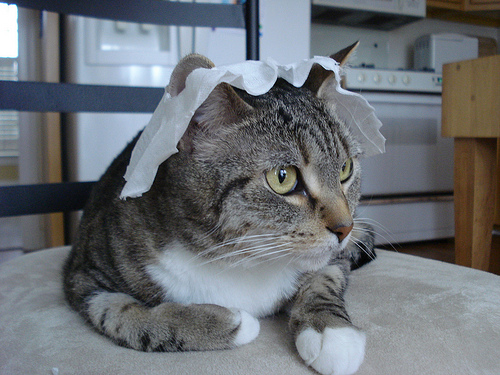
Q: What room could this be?
A: It is a kitchen.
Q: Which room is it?
A: It is a kitchen.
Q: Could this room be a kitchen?
A: Yes, it is a kitchen.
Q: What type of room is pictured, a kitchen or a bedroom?
A: It is a kitchen.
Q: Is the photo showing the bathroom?
A: No, the picture is showing the kitchen.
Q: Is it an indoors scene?
A: Yes, it is indoors.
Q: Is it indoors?
A: Yes, it is indoors.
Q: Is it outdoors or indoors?
A: It is indoors.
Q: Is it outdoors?
A: No, it is indoors.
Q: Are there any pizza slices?
A: No, there are no pizza slices.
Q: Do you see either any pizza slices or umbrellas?
A: No, there are no pizza slices or umbrellas.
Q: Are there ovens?
A: Yes, there is an oven.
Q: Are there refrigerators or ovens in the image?
A: Yes, there is an oven.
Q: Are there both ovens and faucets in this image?
A: No, there is an oven but no faucets.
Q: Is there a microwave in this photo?
A: No, there are no microwaves.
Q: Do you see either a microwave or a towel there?
A: No, there are no microwaves or towels.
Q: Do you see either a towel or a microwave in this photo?
A: No, there are no microwaves or towels.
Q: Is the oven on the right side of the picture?
A: Yes, the oven is on the right of the image.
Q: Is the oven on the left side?
A: No, the oven is on the right of the image.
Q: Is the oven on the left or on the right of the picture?
A: The oven is on the right of the image.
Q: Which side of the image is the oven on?
A: The oven is on the right of the image.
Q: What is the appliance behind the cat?
A: The appliance is an oven.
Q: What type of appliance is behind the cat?
A: The appliance is an oven.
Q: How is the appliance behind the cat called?
A: The appliance is an oven.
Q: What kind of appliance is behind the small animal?
A: The appliance is an oven.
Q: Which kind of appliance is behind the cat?
A: The appliance is an oven.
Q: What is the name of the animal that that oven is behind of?
A: The animal is a cat.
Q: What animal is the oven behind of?
A: The oven is behind the cat.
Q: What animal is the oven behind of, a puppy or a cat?
A: The oven is behind a cat.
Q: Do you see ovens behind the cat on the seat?
A: Yes, there is an oven behind the cat.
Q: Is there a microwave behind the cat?
A: No, there is an oven behind the cat.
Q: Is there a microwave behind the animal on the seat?
A: No, there is an oven behind the cat.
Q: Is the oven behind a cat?
A: Yes, the oven is behind a cat.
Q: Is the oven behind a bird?
A: No, the oven is behind a cat.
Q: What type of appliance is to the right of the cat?
A: The appliance is an oven.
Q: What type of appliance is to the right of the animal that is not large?
A: The appliance is an oven.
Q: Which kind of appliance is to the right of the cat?
A: The appliance is an oven.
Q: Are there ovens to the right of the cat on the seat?
A: Yes, there is an oven to the right of the cat.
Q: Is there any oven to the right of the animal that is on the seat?
A: Yes, there is an oven to the right of the cat.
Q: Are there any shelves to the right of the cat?
A: No, there is an oven to the right of the cat.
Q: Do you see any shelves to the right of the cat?
A: No, there is an oven to the right of the cat.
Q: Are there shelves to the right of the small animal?
A: No, there is an oven to the right of the cat.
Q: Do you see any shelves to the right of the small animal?
A: No, there is an oven to the right of the cat.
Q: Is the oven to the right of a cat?
A: Yes, the oven is to the right of a cat.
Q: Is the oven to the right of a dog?
A: No, the oven is to the right of a cat.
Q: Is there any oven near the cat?
A: Yes, there is an oven near the cat.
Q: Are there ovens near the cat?
A: Yes, there is an oven near the cat.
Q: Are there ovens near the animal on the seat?
A: Yes, there is an oven near the cat.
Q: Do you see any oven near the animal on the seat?
A: Yes, there is an oven near the cat.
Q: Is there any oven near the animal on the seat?
A: Yes, there is an oven near the cat.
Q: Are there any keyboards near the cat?
A: No, there is an oven near the cat.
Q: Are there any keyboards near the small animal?
A: No, there is an oven near the cat.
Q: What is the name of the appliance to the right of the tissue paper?
A: The appliance is an oven.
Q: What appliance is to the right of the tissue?
A: The appliance is an oven.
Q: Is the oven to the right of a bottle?
A: No, the oven is to the right of the tissue paper.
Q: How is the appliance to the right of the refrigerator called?
A: The appliance is an oven.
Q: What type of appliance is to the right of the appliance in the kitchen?
A: The appliance is an oven.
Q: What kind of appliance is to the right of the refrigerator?
A: The appliance is an oven.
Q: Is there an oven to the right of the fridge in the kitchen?
A: Yes, there is an oven to the right of the fridge.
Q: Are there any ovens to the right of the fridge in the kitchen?
A: Yes, there is an oven to the right of the fridge.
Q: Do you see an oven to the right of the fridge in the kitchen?
A: Yes, there is an oven to the right of the fridge.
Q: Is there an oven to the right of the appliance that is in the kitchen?
A: Yes, there is an oven to the right of the fridge.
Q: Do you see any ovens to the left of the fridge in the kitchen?
A: No, the oven is to the right of the freezer.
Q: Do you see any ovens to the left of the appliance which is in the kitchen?
A: No, the oven is to the right of the freezer.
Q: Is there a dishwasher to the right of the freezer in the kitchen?
A: No, there is an oven to the right of the fridge.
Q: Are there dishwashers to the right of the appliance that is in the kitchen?
A: No, there is an oven to the right of the fridge.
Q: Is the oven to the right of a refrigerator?
A: Yes, the oven is to the right of a refrigerator.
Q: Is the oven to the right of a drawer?
A: No, the oven is to the right of a refrigerator.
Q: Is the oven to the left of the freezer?
A: No, the oven is to the right of the freezer.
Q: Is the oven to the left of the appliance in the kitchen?
A: No, the oven is to the right of the freezer.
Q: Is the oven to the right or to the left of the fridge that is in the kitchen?
A: The oven is to the right of the refrigerator.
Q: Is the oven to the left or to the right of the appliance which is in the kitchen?
A: The oven is to the right of the refrigerator.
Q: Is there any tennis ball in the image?
A: No, there are no tennis balls.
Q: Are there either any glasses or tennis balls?
A: No, there are no tennis balls or glasses.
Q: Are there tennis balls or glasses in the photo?
A: No, there are no tennis balls or glasses.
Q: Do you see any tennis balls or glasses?
A: No, there are no tennis balls or glasses.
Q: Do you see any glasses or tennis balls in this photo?
A: No, there are no tennis balls or glasses.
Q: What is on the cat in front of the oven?
A: The tissue paper is on the cat.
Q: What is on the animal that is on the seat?
A: The tissue paper is on the cat.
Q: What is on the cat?
A: The tissue paper is on the cat.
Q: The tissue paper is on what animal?
A: The tissue paper is on the cat.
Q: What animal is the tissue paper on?
A: The tissue paper is on the cat.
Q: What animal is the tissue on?
A: The tissue paper is on the cat.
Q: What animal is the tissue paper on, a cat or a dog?
A: The tissue paper is on a cat.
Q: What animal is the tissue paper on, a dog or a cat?
A: The tissue paper is on a cat.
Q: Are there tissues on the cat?
A: Yes, there is a tissue on the cat.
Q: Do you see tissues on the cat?
A: Yes, there is a tissue on the cat.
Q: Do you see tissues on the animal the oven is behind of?
A: Yes, there is a tissue on the cat.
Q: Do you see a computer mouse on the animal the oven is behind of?
A: No, there is a tissue on the cat.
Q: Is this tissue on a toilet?
A: No, the tissue is on a cat.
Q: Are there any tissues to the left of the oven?
A: Yes, there is a tissue to the left of the oven.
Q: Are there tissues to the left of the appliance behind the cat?
A: Yes, there is a tissue to the left of the oven.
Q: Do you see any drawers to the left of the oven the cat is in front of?
A: No, there is a tissue to the left of the oven.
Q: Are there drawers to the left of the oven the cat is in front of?
A: No, there is a tissue to the left of the oven.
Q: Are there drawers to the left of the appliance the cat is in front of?
A: No, there is a tissue to the left of the oven.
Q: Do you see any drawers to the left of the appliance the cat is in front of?
A: No, there is a tissue to the left of the oven.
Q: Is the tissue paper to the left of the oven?
A: Yes, the tissue paper is to the left of the oven.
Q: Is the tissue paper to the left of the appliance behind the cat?
A: Yes, the tissue paper is to the left of the oven.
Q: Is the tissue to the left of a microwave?
A: No, the tissue is to the left of the oven.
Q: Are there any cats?
A: Yes, there is a cat.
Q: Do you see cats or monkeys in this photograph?
A: Yes, there is a cat.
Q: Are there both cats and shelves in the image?
A: No, there is a cat but no shelves.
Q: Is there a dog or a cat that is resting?
A: Yes, the cat is resting.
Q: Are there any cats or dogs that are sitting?
A: Yes, the cat is sitting.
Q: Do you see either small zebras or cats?
A: Yes, there is a small cat.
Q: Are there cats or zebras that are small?
A: Yes, the cat is small.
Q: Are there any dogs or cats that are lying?
A: Yes, the cat is lying.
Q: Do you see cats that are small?
A: Yes, there is a small cat.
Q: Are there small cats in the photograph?
A: Yes, there is a small cat.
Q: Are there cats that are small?
A: Yes, there is a cat that is small.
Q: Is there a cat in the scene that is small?
A: Yes, there is a cat that is small.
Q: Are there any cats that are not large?
A: Yes, there is a small cat.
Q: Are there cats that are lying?
A: Yes, there is a cat that is lying.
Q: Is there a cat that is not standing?
A: Yes, there is a cat that is lying.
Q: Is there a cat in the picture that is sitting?
A: Yes, there is a cat that is sitting.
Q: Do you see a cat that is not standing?
A: Yes, there is a cat that is sitting .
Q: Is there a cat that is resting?
A: Yes, there is a cat that is resting.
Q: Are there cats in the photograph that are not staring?
A: Yes, there is a cat that is resting.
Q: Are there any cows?
A: No, there are no cows.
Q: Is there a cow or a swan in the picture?
A: No, there are no cows or swans.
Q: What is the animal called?
A: The animal is a cat.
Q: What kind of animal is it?
A: The animal is a cat.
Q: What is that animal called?
A: This is a cat.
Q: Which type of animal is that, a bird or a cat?
A: This is a cat.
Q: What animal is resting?
A: The animal is a cat.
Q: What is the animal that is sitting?
A: The animal is a cat.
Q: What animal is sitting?
A: The animal is a cat.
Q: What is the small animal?
A: The animal is a cat.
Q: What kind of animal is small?
A: The animal is a cat.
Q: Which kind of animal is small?
A: The animal is a cat.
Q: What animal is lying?
A: The animal is a cat.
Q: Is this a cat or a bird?
A: This is a cat.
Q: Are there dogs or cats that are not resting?
A: No, there is a cat but it is resting.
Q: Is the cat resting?
A: Yes, the cat is resting.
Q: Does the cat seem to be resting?
A: Yes, the cat is resting.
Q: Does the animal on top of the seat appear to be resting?
A: Yes, the cat is resting.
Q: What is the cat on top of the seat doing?
A: The cat is resting.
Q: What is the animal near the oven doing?
A: The cat is resting.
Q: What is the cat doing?
A: The cat is resting.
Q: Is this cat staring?
A: No, the cat is resting.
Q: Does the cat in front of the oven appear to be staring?
A: No, the cat is resting.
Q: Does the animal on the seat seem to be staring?
A: No, the cat is resting.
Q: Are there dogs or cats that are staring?
A: No, there is a cat but it is resting.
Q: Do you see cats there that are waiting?
A: No, there is a cat but it is resting.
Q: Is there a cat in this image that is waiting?
A: No, there is a cat but it is resting.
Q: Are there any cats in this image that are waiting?
A: No, there is a cat but it is resting.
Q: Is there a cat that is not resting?
A: No, there is a cat but it is resting.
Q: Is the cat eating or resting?
A: The cat is resting.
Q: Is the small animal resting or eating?
A: The cat is resting.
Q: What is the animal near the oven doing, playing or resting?
A: The cat is resting.